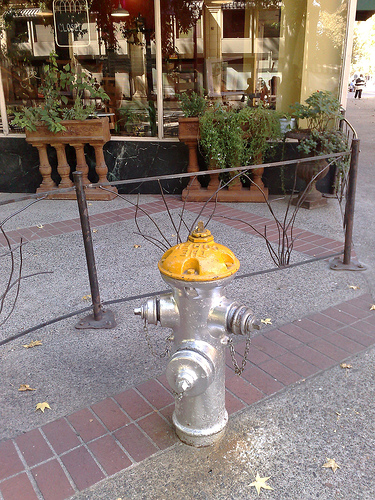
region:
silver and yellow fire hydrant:
[133, 222, 266, 445]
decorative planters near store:
[20, 50, 352, 196]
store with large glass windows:
[0, 2, 352, 194]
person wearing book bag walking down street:
[351, 72, 368, 98]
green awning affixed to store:
[353, 0, 373, 25]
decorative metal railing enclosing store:
[0, 106, 365, 344]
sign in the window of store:
[52, 0, 92, 48]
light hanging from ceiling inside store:
[111, 0, 130, 19]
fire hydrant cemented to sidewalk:
[133, 223, 263, 447]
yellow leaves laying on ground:
[251, 281, 373, 495]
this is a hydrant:
[154, 217, 253, 462]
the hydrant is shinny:
[181, 315, 215, 334]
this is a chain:
[218, 338, 252, 374]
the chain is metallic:
[226, 342, 257, 370]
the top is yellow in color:
[180, 245, 225, 271]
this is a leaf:
[246, 471, 275, 497]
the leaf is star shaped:
[239, 467, 280, 494]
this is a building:
[227, 23, 326, 72]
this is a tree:
[307, 87, 358, 181]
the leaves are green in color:
[315, 94, 326, 113]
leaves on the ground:
[13, 339, 62, 435]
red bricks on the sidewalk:
[58, 392, 146, 480]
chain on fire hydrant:
[223, 318, 274, 383]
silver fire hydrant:
[141, 291, 249, 440]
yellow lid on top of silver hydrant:
[154, 220, 235, 284]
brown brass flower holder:
[21, 115, 126, 201]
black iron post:
[61, 169, 108, 325]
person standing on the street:
[352, 73, 365, 98]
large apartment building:
[92, 23, 294, 94]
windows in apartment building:
[217, 51, 250, 92]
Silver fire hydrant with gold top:
[160, 223, 247, 362]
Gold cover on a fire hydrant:
[163, 226, 223, 291]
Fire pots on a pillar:
[175, 92, 271, 173]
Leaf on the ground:
[244, 465, 282, 496]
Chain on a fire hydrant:
[215, 323, 258, 384]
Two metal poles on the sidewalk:
[57, 143, 372, 278]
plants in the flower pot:
[31, 86, 114, 143]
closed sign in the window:
[47, 6, 91, 49]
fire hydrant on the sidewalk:
[130, 231, 252, 446]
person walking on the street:
[353, 61, 373, 119]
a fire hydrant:
[133, 217, 273, 451]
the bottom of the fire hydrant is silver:
[127, 219, 272, 448]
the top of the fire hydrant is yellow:
[120, 215, 267, 449]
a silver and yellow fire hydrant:
[122, 216, 267, 455]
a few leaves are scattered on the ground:
[25, 284, 373, 495]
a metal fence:
[0, 142, 365, 343]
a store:
[6, 2, 364, 201]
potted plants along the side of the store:
[17, 58, 336, 212]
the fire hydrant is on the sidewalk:
[108, 226, 297, 477]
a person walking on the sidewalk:
[352, 66, 371, 106]